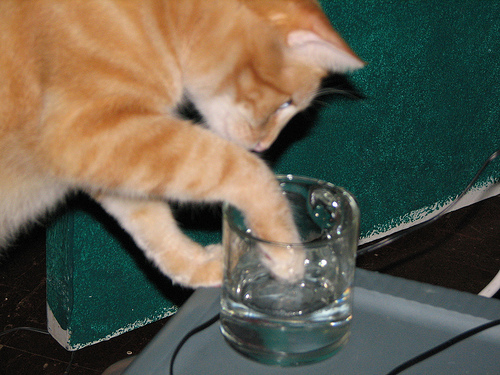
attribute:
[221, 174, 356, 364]
glass — clear, for drinking, partially filled, atop storage tub, in scene, completely clear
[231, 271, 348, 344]
water — inside a glass, shallow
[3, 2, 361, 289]
cat — orange, a tabby, yellow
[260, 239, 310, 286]
paw — inside the glass, inside the cup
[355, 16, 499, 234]
wall — covered in paper, green wallpaper, green, painted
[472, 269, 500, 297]
power cord — white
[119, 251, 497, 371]
storage lid — grey, grey plastic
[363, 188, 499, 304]
floor — dark, tiled, brown, black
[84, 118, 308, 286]
front legs — a pair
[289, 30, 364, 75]
ear — pointy